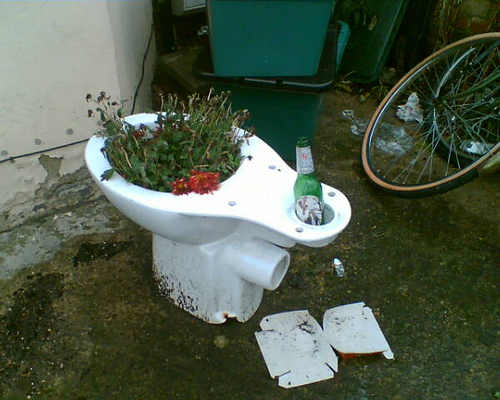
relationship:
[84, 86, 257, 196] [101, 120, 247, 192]
plant growing out of bowl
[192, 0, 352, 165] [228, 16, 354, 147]
bins of bin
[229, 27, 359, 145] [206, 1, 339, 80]
bins of bin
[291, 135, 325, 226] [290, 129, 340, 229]
beer bottle of alcohol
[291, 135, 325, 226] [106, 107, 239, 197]
beer bottle in bowl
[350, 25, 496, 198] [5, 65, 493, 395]
bike tire in yard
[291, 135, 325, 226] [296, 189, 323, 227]
beer bottle of beer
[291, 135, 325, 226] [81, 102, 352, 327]
beer bottle in toilet bowl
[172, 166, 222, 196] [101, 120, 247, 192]
flower in bowl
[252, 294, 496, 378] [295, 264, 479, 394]
trash on ground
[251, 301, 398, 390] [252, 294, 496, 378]
party cups of trash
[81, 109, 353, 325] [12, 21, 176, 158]
toilet placed by wall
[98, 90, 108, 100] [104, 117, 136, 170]
flower on stem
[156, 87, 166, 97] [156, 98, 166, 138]
flower on stem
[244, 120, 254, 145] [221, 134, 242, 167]
flower on stem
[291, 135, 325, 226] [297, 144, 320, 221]
beer bottle with labels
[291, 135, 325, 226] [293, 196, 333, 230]
beer bottle in toilet hole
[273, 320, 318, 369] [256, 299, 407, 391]
inside of container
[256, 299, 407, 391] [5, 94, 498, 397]
container on ground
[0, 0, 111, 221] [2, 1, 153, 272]
paint on wall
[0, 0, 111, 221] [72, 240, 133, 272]
paint over shape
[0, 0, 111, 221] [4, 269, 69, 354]
paint over shape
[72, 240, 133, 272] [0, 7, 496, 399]
shape on ground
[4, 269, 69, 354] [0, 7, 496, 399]
shape on ground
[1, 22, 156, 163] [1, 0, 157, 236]
wires along edge of wall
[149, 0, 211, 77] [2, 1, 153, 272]
space between wall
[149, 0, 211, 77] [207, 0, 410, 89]
space between containers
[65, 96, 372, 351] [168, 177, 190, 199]
toilet with flower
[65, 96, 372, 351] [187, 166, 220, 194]
toilet with flower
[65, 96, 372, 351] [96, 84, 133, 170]
toilet with flower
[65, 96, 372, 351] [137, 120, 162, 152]
toilet with flower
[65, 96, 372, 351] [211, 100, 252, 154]
toilet with flower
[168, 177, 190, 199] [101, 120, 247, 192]
flower inside bowl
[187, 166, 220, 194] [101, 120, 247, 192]
flower inside bowl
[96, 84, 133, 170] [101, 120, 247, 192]
flower inside bowl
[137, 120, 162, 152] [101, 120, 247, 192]
flower inside bowl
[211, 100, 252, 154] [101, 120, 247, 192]
flower inside bowl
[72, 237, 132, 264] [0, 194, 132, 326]
hole at base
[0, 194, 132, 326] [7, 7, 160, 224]
base of wall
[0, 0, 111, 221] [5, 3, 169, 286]
paint on wall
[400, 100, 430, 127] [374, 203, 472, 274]
trash on ground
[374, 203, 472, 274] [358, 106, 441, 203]
ground near bike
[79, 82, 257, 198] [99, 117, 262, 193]
plant in bowl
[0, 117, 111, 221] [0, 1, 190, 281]
paint on wall